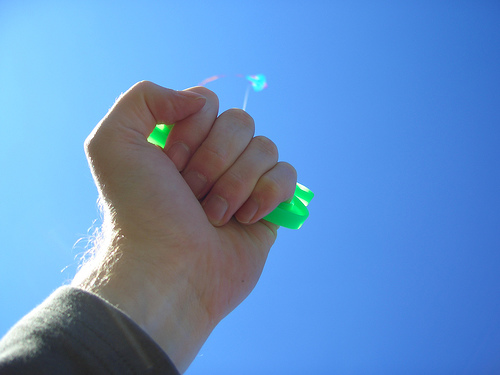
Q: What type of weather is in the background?
A: It is clear.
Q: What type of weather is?
A: It is clear.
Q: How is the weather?
A: It is clear.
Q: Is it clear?
A: Yes, it is clear.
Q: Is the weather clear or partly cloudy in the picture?
A: It is clear.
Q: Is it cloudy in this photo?
A: No, it is clear.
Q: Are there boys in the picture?
A: No, there are no boys.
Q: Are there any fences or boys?
A: No, there are no boys or fences.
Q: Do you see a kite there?
A: Yes, there is a kite.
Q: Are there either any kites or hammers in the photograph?
A: Yes, there is a kite.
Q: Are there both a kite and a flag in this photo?
A: No, there is a kite but no flags.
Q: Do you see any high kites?
A: Yes, there is a high kite.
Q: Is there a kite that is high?
A: Yes, there is a kite that is high.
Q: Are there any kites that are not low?
A: Yes, there is a high kite.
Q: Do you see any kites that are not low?
A: Yes, there is a high kite.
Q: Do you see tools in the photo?
A: No, there are no tools.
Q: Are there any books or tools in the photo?
A: No, there are no tools or books.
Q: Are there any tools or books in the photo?
A: No, there are no tools or books.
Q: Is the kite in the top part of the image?
A: Yes, the kite is in the top of the image.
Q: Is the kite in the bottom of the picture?
A: No, the kite is in the top of the image.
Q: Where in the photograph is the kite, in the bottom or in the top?
A: The kite is in the top of the image.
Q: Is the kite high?
A: Yes, the kite is high.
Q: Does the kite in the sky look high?
A: Yes, the kite is high.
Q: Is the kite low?
A: No, the kite is high.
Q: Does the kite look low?
A: No, the kite is high.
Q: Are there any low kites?
A: No, there is a kite but it is high.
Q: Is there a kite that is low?
A: No, there is a kite but it is high.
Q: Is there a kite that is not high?
A: No, there is a kite but it is high.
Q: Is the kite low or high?
A: The kite is high.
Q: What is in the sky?
A: The kite is in the sky.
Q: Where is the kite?
A: The kite is in the sky.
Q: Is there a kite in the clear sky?
A: Yes, there is a kite in the sky.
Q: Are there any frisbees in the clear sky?
A: No, there is a kite in the sky.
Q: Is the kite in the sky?
A: Yes, the kite is in the sky.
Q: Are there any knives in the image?
A: Yes, there is a knife.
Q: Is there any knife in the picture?
A: Yes, there is a knife.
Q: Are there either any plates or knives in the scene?
A: Yes, there is a knife.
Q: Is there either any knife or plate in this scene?
A: Yes, there is a knife.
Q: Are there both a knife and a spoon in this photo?
A: No, there is a knife but no spoons.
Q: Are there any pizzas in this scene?
A: No, there are no pizzas.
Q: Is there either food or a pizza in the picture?
A: No, there are no pizzas or food.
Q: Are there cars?
A: No, there are no cars.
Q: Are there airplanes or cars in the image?
A: No, there are no cars or airplanes.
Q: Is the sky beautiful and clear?
A: Yes, the sky is beautiful and clear.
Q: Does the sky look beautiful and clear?
A: Yes, the sky is beautiful and clear.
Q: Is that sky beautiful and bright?
A: Yes, the sky is beautiful and bright.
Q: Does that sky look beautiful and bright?
A: Yes, the sky is beautiful and bright.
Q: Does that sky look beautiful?
A: Yes, the sky is beautiful.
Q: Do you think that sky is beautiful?
A: Yes, the sky is beautiful.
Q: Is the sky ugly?
A: No, the sky is beautiful.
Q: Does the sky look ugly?
A: No, the sky is beautiful.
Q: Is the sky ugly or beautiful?
A: The sky is beautiful.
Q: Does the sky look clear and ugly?
A: No, the sky is clear but beautiful.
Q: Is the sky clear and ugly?
A: No, the sky is clear but beautiful.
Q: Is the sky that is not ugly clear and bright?
A: Yes, the sky is clear and bright.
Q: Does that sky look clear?
A: Yes, the sky is clear.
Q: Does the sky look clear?
A: Yes, the sky is clear.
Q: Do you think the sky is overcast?
A: No, the sky is clear.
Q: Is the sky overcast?
A: No, the sky is clear.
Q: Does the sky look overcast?
A: No, the sky is clear.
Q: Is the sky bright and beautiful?
A: Yes, the sky is bright and beautiful.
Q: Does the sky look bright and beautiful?
A: Yes, the sky is bright and beautiful.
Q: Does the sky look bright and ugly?
A: No, the sky is bright but beautiful.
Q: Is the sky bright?
A: Yes, the sky is bright.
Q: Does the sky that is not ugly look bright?
A: Yes, the sky is bright.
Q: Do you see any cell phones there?
A: No, there are no cell phones.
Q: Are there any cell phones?
A: No, there are no cell phones.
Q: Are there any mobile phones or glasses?
A: No, there are no mobile phones or glasses.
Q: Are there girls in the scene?
A: No, there are no girls.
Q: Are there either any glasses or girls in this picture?
A: No, there are no girls or glasses.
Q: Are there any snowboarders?
A: No, there are no snowboarders.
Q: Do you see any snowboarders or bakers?
A: No, there are no snowboarders or bakers.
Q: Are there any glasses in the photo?
A: No, there are no glasses.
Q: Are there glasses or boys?
A: No, there are no glasses or boys.